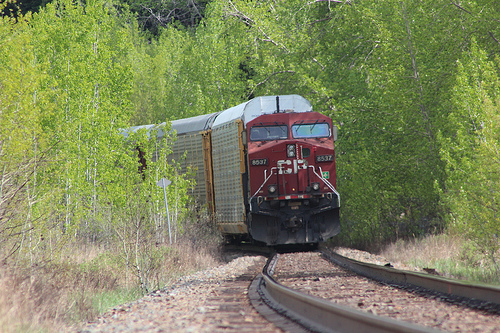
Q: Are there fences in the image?
A: No, there are no fences.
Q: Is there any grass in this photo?
A: Yes, there is grass.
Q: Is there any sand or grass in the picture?
A: Yes, there is grass.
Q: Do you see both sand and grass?
A: No, there is grass but no sand.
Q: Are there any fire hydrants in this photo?
A: No, there are no fire hydrants.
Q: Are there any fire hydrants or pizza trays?
A: No, there are no fire hydrants or pizza trays.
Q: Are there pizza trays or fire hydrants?
A: No, there are no fire hydrants or pizza trays.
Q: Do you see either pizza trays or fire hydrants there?
A: No, there are no fire hydrants or pizza trays.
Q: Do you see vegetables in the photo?
A: Yes, there are vegetables.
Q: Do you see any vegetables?
A: Yes, there are vegetables.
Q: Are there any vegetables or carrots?
A: Yes, there are vegetables.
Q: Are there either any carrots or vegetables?
A: Yes, there are vegetables.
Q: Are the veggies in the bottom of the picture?
A: Yes, the veggies are in the bottom of the image.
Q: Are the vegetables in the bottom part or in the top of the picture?
A: The vegetables are in the bottom of the image.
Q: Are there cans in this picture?
A: No, there are no cans.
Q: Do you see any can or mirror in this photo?
A: No, there are no cans or mirrors.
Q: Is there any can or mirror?
A: No, there are no cans or mirrors.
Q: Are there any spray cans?
A: No, there are no spray cans.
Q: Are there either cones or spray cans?
A: No, there are no spray cans or cones.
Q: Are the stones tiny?
A: Yes, the stones are tiny.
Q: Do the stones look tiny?
A: Yes, the stones are tiny.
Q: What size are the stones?
A: The stones are tiny.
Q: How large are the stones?
A: The stones are tiny.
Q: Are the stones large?
A: No, the stones are tiny.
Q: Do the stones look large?
A: No, the stones are tiny.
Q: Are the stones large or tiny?
A: The stones are tiny.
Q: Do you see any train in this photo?
A: Yes, there is a train.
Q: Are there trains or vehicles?
A: Yes, there is a train.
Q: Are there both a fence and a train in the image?
A: No, there is a train but no fences.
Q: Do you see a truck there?
A: No, there are no trucks.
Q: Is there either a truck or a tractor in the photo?
A: No, there are no trucks or tractors.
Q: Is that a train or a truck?
A: That is a train.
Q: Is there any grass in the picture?
A: Yes, there is grass.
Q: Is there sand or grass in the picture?
A: Yes, there is grass.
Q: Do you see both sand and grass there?
A: No, there is grass but no sand.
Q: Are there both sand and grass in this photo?
A: No, there is grass but no sand.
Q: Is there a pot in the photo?
A: No, there are no pots.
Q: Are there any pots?
A: No, there are no pots.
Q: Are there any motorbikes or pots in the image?
A: No, there are no pots or motorbikes.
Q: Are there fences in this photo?
A: No, there are no fences.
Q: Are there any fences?
A: No, there are no fences.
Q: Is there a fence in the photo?
A: No, there are no fences.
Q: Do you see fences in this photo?
A: No, there are no fences.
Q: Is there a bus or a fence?
A: No, there are no fences or buses.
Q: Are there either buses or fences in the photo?
A: No, there are no fences or buses.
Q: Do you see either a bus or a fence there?
A: No, there are no fences or buses.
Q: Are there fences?
A: No, there are no fences.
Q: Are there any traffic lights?
A: No, there are no traffic lights.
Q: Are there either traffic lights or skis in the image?
A: No, there are no traffic lights or skis.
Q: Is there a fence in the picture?
A: No, there are no fences.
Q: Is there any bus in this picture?
A: No, there are no buses.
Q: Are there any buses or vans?
A: No, there are no buses or vans.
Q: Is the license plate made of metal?
A: Yes, the license plate is made of metal.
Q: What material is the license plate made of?
A: The license plate is made of metal.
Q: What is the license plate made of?
A: The license plate is made of metal.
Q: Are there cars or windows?
A: Yes, there is a window.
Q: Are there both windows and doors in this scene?
A: No, there is a window but no doors.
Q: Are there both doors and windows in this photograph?
A: No, there is a window but no doors.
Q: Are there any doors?
A: No, there are no doors.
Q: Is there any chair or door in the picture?
A: No, there are no doors or chairs.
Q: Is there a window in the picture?
A: Yes, there is a window.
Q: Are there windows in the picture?
A: Yes, there is a window.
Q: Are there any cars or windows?
A: Yes, there is a window.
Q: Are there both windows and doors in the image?
A: No, there is a window but no doors.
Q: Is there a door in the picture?
A: No, there are no doors.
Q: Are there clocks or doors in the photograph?
A: No, there are no doors or clocks.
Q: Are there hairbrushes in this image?
A: No, there are no hairbrushes.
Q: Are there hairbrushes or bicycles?
A: No, there are no hairbrushes or bicycles.